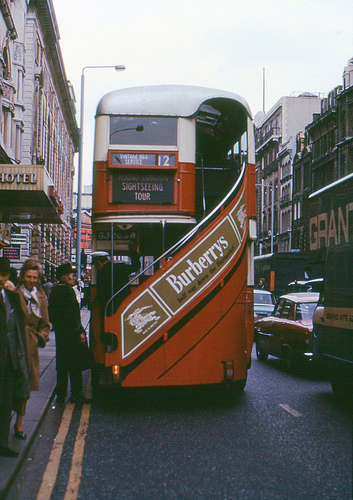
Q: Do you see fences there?
A: No, there are no fences.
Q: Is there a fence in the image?
A: No, there are no fences.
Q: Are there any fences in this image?
A: No, there are no fences.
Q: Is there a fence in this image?
A: No, there are no fences.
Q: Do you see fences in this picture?
A: No, there are no fences.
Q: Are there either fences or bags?
A: No, there are no fences or bags.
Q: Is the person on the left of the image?
A: Yes, the person is on the left of the image.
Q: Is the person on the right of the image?
A: No, the person is on the left of the image.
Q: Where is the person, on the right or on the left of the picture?
A: The person is on the left of the image.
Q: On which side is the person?
A: The person is on the left of the image.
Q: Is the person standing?
A: Yes, the person is standing.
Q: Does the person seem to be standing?
A: Yes, the person is standing.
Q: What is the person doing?
A: The person is standing.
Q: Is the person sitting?
A: No, the person is standing.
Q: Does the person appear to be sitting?
A: No, the person is standing.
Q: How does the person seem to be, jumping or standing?
A: The person is standing.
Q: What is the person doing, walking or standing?
A: The person is standing.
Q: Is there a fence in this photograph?
A: No, there are no fences.